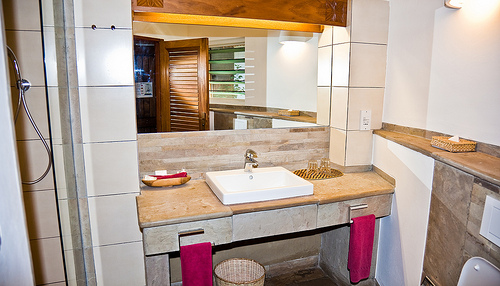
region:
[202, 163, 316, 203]
a large white bathroom sink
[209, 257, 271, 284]
part of a wooden basket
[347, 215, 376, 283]
a long pink towel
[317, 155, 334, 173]
a clear cup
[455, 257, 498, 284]
part of a white toilet seat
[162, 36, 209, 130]
part of a wooden brown door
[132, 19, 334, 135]
a large bathroom mirror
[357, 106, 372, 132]
a white wall switch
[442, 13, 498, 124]
a white painted wall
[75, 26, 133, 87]
part of a white tile wall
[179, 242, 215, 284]
A violet towel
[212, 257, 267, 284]
A basket on the ground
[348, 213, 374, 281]
A hanging violet towel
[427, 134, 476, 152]
A napkin holder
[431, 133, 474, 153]
A tissue dispenser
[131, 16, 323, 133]
A mirror in a bathroom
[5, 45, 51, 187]
A shower hose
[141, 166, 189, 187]
A washcloth and soap container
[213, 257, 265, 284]
A waste basket in a bathroom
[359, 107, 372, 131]
A light switch on a wall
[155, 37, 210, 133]
thats a wood door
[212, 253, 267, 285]
this is a straw basket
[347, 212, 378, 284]
this a red towel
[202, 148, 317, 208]
this is a white sink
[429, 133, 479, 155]
this is a tissue box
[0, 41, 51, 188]
this is the shower cord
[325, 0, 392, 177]
this is the wall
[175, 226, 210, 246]
thats a towel holder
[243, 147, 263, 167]
thats a silver faucet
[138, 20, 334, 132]
thats a large mirror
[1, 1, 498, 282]
A neat and tidy bathroom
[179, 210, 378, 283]
Two hanging pink towels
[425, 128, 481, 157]
A box of tissues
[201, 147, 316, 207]
A faucet over a sink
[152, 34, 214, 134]
A brown wooden door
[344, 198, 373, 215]
Handle on a drawer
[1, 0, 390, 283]
Tiles on the walls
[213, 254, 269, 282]
A round trash can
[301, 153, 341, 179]
Two glasses on the countertop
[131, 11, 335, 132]
Reflections in the mirror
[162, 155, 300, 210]
a white basin in room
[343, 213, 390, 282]
a towel in room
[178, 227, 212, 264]
a part of towel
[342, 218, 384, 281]
pink towel in the room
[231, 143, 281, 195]
a water tap in room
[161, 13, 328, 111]
a mirror on the wall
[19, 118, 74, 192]
a wire in the door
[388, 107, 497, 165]
a table on the side